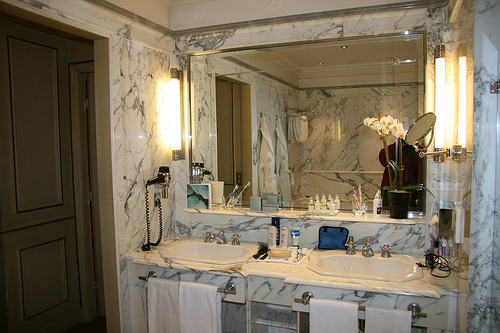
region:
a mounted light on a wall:
[159, 57, 188, 166]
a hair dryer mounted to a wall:
[143, 154, 172, 243]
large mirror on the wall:
[186, 21, 430, 190]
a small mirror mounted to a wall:
[397, 106, 449, 178]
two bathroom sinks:
[153, 224, 423, 291]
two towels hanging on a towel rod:
[131, 278, 231, 311]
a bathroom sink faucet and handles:
[339, 232, 405, 257]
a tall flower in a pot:
[379, 97, 415, 233]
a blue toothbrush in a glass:
[225, 176, 246, 218]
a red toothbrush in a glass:
[347, 180, 368, 206]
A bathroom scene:
[0, 0, 498, 331]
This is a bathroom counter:
[131, 233, 463, 331]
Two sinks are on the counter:
[159, 225, 424, 282]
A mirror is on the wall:
[186, 28, 428, 219]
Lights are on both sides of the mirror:
[160, 41, 451, 161]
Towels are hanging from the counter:
[131, 272, 429, 331]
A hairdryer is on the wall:
[141, 162, 172, 202]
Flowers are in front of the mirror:
[363, 111, 411, 219]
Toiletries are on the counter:
[261, 215, 302, 261]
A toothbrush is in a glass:
[220, 180, 240, 209]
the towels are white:
[132, 271, 419, 331]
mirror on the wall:
[394, 99, 446, 160]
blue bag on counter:
[298, 211, 364, 249]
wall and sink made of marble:
[22, 1, 495, 331]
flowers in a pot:
[363, 99, 418, 224]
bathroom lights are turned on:
[146, 50, 498, 209]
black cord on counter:
[417, 247, 454, 282]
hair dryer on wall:
[126, 150, 186, 252]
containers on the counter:
[271, 208, 323, 260]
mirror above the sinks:
[175, 38, 437, 220]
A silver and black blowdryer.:
[135, 164, 171, 252]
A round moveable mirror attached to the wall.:
[404, 106, 453, 161]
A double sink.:
[144, 222, 438, 303]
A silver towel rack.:
[137, 272, 239, 296]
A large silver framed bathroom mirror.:
[183, 29, 428, 218]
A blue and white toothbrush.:
[226, 182, 241, 204]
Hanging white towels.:
[142, 279, 419, 331]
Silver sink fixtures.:
[202, 224, 394, 258]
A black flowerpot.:
[385, 192, 410, 217]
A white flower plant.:
[360, 104, 419, 219]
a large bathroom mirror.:
[179, 29, 435, 224]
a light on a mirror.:
[141, 60, 195, 180]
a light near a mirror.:
[386, 33, 482, 171]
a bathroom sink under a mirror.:
[140, 212, 252, 280]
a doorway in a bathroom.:
[4, 12, 114, 331]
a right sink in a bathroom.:
[306, 245, 423, 302]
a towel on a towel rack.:
[301, 279, 369, 331]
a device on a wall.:
[109, 160, 175, 261]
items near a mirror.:
[423, 198, 469, 302]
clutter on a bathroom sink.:
[238, 200, 312, 265]